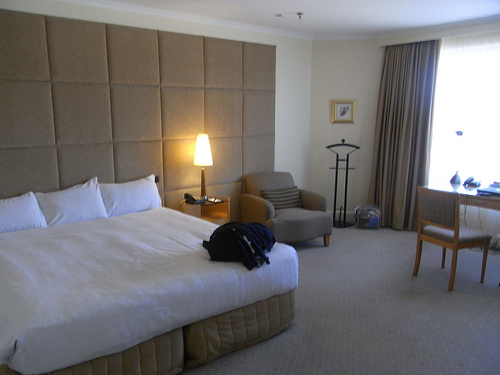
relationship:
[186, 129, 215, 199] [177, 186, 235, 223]
lamp on table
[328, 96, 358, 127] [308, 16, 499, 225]
picture on wall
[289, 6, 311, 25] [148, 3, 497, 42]
sprinkler on ceiling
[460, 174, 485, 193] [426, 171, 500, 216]
phone on desk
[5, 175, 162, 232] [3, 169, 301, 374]
pillows on bed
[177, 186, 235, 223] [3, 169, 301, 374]
nightstand next to bed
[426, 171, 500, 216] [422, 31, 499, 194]
desk near window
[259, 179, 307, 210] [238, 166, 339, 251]
pillow on chair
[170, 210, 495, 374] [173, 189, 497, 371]
carpet on ground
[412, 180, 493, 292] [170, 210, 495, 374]
chair on floor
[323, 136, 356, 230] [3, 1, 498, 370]
coat rack in room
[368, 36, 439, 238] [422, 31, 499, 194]
curtains on window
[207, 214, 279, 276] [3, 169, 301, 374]
clothes on bed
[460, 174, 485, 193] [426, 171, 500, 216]
phone on table